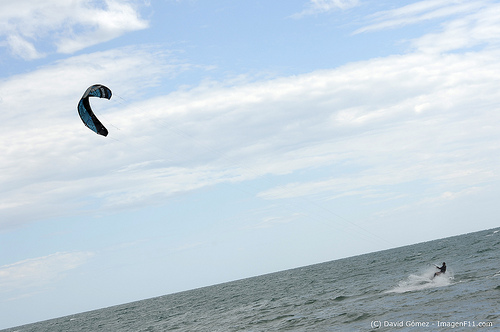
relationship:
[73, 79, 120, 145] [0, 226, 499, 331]
parasail above water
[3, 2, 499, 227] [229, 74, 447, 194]
sky with clouds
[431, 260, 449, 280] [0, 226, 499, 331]
person in ocean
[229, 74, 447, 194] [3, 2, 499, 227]
clouds in sky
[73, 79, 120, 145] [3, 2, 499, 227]
parasail in sky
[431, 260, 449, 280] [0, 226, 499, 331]
man in ocean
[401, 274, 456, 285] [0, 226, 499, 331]
spray rising from water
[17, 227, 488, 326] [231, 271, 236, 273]
horizon in distance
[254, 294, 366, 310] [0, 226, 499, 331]
waves forming on water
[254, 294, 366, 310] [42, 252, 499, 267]
waves cresting in background